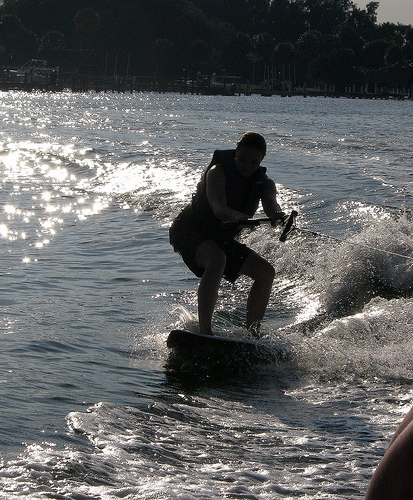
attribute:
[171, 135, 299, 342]
man — surfing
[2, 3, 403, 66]
shoreline — green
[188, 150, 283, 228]
vest — black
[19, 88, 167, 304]
water — white, blue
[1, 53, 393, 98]
dock — wood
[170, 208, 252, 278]
shorts — black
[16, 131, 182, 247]
waves — sea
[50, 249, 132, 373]
sea — calm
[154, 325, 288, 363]
surfboard — blue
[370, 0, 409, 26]
sky — gray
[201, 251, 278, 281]
knees — bending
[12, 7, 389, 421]
season — summer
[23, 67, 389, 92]
docks — wooden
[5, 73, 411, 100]
dock — wooden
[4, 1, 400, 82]
trees — large